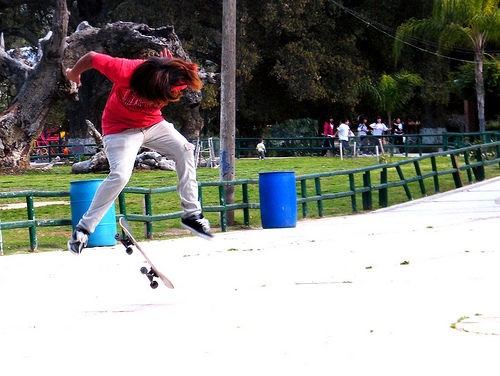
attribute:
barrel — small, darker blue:
[259, 172, 298, 228]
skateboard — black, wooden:
[120, 218, 175, 298]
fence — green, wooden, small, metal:
[4, 157, 499, 243]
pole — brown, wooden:
[221, 4, 237, 223]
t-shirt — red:
[97, 57, 163, 123]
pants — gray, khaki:
[69, 130, 209, 222]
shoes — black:
[65, 228, 92, 257]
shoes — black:
[179, 214, 217, 242]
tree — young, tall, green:
[450, 1, 499, 137]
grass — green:
[0, 175, 74, 191]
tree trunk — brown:
[9, 73, 50, 148]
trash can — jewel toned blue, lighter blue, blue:
[71, 182, 116, 246]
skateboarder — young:
[64, 46, 223, 259]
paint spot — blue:
[222, 148, 231, 177]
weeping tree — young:
[367, 72, 408, 160]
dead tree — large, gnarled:
[0, 30, 57, 171]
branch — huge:
[67, 121, 212, 171]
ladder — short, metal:
[193, 138, 217, 170]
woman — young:
[323, 116, 338, 156]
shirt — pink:
[324, 123, 335, 139]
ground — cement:
[44, 270, 490, 367]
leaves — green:
[278, 68, 290, 77]